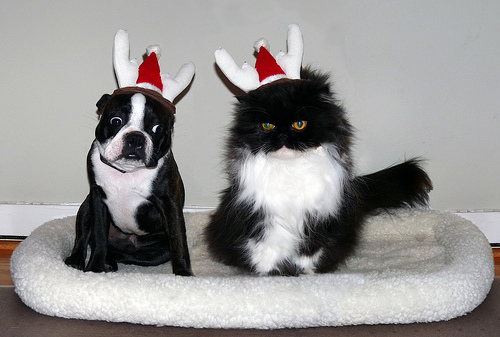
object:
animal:
[67, 91, 194, 276]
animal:
[203, 64, 433, 276]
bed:
[9, 208, 494, 330]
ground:
[0, 240, 500, 286]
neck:
[235, 145, 345, 167]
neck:
[91, 141, 174, 174]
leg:
[63, 195, 94, 271]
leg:
[84, 181, 107, 271]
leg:
[157, 193, 193, 276]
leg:
[103, 255, 118, 273]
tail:
[354, 156, 432, 217]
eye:
[108, 116, 121, 126]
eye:
[152, 124, 162, 134]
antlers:
[112, 30, 198, 115]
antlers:
[214, 24, 303, 95]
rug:
[0, 276, 499, 337]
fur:
[240, 167, 346, 276]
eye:
[261, 121, 275, 130]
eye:
[293, 121, 305, 130]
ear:
[96, 94, 109, 112]